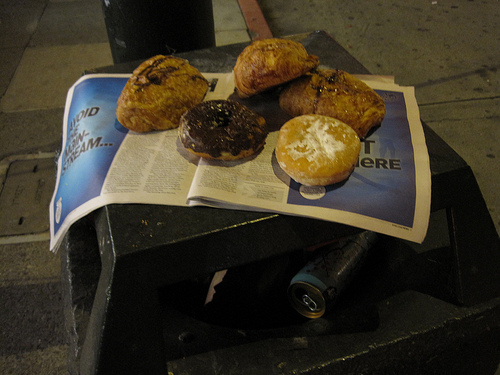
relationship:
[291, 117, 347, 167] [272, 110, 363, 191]
powder on doughnut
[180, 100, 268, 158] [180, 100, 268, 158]
chocolate covered in chocolate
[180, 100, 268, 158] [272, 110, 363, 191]
chocolate next to doughnut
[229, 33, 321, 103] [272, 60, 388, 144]
donut leaning on donut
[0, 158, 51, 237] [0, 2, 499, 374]
sewer cover on ground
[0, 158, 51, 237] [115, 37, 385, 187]
sewer cover to left of donuts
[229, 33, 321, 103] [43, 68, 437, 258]
donut on newspaper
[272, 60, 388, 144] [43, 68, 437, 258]
donut on newspaper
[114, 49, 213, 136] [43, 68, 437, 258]
donut on newspaper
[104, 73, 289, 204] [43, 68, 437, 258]
area on newspaper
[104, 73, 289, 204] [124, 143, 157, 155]
area has letters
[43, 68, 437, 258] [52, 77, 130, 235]
newspaper has left side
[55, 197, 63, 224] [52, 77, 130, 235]
design label on left side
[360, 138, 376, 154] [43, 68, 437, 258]
t printed on newspaper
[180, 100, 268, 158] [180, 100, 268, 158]
chocolate has chocolate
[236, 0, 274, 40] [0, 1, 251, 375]
stripe on sidewalk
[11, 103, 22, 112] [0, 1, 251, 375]
spot on sidewalk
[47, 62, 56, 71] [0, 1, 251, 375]
spot on sidewalk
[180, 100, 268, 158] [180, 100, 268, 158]
chocolate covered with chocolate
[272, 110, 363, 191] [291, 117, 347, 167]
doughnut has powder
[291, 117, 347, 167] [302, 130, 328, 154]
powder on center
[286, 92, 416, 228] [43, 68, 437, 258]
ad on newspaper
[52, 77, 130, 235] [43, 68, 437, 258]
left side on newspaper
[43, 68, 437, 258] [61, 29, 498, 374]
newspaper over trash can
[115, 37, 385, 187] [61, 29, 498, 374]
donuts are over trash can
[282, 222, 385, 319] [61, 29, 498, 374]
can in trash can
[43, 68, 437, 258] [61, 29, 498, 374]
newspaper on trash can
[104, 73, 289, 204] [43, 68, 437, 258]
area in newspaper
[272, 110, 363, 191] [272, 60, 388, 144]
doughnut next to donut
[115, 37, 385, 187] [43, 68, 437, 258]
donuts are on newspaper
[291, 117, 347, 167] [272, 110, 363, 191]
powder on top of doughnut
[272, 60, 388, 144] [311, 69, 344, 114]
donut has drizzle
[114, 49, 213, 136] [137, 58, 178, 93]
donut has drizzle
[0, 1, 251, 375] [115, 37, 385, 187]
sidewalk to left of donuts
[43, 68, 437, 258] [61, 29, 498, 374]
newspaper resting on trash can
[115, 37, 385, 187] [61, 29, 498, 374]
donuts are resting on trash can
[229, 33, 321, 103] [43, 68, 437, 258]
donut placed on newspaper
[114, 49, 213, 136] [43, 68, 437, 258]
donut placed on newspaper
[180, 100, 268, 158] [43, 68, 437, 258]
chocolate placed on newspaper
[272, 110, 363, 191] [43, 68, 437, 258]
doughnut placed on newspaper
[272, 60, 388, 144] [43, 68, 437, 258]
donut placed on newspaper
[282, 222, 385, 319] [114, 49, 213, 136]
can under donut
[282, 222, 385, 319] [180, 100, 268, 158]
can under chocolate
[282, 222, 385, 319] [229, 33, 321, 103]
can under donut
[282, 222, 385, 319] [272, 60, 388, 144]
can under donut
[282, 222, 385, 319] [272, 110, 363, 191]
can under doughnut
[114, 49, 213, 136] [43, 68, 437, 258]
donut over a newspaper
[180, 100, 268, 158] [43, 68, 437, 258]
chocolate over a newspaper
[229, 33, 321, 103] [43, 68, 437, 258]
donut over a newspaper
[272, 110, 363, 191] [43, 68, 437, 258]
doughnut over a newspaper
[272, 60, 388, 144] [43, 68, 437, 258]
donut over a newspaper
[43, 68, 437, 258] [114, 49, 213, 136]
newspaper under donut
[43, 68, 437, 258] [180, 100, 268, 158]
newspaper under chocolate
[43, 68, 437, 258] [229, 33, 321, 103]
newspaper under donut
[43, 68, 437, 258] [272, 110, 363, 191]
newspaper under doughnut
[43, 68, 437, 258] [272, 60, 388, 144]
newspaper under donut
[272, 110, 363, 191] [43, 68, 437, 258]
doughnut sitting on newspaper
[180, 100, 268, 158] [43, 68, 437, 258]
chocolate sitting on newspaper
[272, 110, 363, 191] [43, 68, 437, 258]
doughnut on newspaper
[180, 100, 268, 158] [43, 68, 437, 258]
chocolate on newspaper